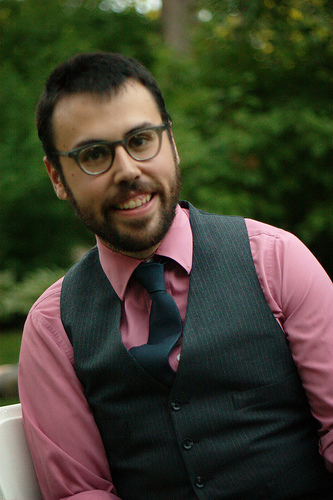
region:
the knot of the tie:
[135, 260, 170, 295]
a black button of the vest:
[180, 434, 195, 453]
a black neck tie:
[127, 260, 185, 389]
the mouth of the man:
[108, 180, 161, 226]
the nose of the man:
[107, 143, 143, 193]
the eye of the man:
[122, 124, 162, 158]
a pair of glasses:
[40, 115, 177, 183]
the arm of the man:
[12, 300, 129, 498]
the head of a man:
[27, 45, 186, 254]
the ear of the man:
[39, 152, 73, 204]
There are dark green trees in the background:
[251, 117, 294, 200]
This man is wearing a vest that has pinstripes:
[235, 347, 273, 424]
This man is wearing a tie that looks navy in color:
[146, 286, 186, 388]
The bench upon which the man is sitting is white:
[9, 447, 24, 491]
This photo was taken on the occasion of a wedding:
[63, 267, 268, 473]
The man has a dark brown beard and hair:
[34, 56, 183, 229]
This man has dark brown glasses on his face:
[63, 124, 165, 174]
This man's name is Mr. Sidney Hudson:
[42, 41, 240, 368]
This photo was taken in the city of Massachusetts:
[34, 41, 264, 369]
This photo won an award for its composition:
[53, 36, 220, 314]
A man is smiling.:
[65, 181, 236, 263]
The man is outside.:
[20, 180, 325, 288]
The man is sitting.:
[22, 213, 312, 474]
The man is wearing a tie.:
[115, 280, 223, 441]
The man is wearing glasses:
[63, 162, 178, 190]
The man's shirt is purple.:
[25, 319, 80, 468]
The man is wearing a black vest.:
[84, 314, 269, 484]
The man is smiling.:
[102, 187, 197, 219]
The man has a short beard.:
[74, 194, 211, 252]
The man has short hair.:
[33, 67, 206, 122]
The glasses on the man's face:
[49, 118, 173, 178]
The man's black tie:
[122, 258, 191, 386]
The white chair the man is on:
[0, 402, 43, 499]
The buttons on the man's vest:
[167, 398, 208, 490]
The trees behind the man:
[1, 1, 332, 409]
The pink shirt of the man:
[14, 204, 330, 498]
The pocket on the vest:
[227, 371, 303, 411]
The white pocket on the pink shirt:
[175, 352, 185, 365]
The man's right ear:
[41, 156, 75, 204]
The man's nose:
[110, 146, 146, 186]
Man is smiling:
[8, 38, 331, 499]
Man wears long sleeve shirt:
[11, 43, 329, 495]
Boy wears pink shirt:
[6, 51, 331, 498]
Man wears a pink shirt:
[7, 42, 328, 496]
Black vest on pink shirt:
[29, 209, 328, 497]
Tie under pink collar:
[121, 255, 190, 379]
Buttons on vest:
[167, 396, 211, 495]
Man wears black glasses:
[14, 35, 212, 276]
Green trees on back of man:
[0, 0, 327, 103]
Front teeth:
[99, 181, 164, 220]